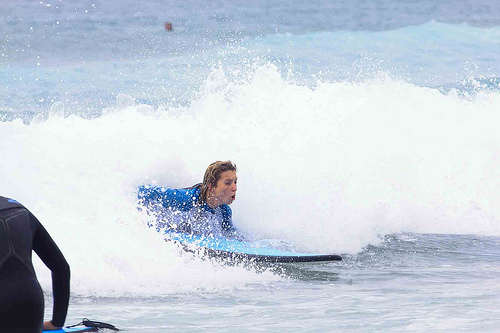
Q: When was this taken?
A: During the day.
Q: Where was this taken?
A: At the beach.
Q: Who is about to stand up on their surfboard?
A: The blonde woman.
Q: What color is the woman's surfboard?
A: Blue.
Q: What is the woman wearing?
A: A wetsuit.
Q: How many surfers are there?
A: Two.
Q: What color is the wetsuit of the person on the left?
A: Black.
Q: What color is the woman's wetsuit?
A: Blue and white.